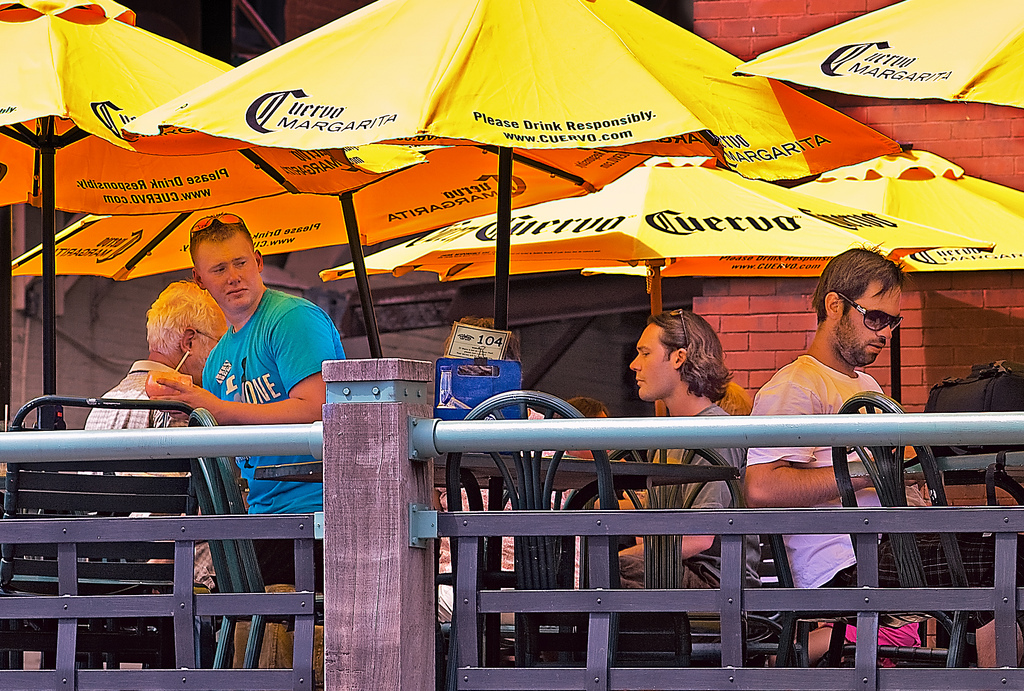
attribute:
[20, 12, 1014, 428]
umbrellas — opened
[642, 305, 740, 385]
hair — grey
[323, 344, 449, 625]
post — wood